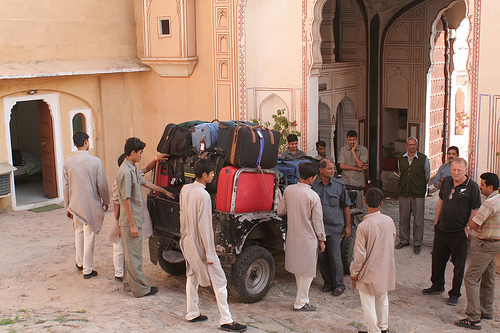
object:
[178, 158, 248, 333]
man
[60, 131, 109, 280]
man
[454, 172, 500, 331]
man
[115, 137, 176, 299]
man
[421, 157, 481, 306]
man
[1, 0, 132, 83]
wall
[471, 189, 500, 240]
shirt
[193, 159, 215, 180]
hair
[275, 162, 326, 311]
man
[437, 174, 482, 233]
black clothing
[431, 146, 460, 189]
man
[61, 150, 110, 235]
tan shirt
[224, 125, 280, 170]
suitcase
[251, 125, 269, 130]
handle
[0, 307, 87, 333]
grass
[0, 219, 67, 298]
ground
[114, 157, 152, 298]
coveralls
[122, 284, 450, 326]
street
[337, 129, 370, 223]
man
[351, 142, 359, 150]
hand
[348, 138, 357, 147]
face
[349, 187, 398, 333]
man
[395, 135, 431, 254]
man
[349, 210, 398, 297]
beige shirt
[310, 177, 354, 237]
gray clothing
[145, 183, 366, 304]
jeep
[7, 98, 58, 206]
door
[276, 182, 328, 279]
shirt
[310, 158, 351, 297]
man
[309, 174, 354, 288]
uniform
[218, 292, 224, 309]
white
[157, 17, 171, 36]
window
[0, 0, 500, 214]
building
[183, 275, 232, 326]
pants